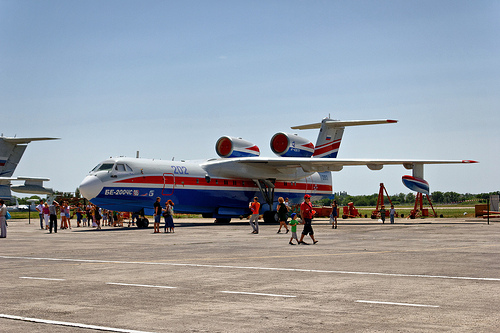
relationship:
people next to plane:
[29, 195, 84, 225] [67, 115, 396, 207]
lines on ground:
[166, 233, 406, 293] [5, 219, 497, 331]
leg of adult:
[310, 229, 317, 241] [297, 193, 319, 244]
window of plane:
[89, 146, 119, 190] [77, 111, 480, 226]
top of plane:
[287, 112, 399, 132] [58, 122, 425, 204]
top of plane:
[97, 120, 440, 170] [77, 111, 480, 226]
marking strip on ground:
[19, 276, 66, 281] [5, 219, 497, 331]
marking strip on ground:
[104, 280, 177, 290] [5, 219, 497, 331]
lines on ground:
[215, 291, 298, 300] [5, 219, 497, 331]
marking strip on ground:
[356, 294, 438, 308] [5, 219, 497, 331]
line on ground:
[0, 253, 500, 283] [5, 219, 497, 331]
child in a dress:
[288, 213, 302, 245] [276, 209, 307, 260]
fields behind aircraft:
[3, 204, 498, 224] [78, 117, 480, 226]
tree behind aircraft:
[73, 187, 81, 204] [78, 117, 480, 226]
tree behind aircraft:
[338, 191, 348, 208] [78, 117, 480, 226]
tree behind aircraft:
[397, 192, 405, 204] [78, 117, 480, 226]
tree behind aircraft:
[406, 193, 414, 203] [78, 117, 480, 226]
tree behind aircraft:
[442, 190, 452, 202] [78, 117, 480, 226]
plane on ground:
[56, 85, 499, 259] [107, 214, 414, 298]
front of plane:
[76, 154, 146, 213] [77, 111, 480, 226]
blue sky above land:
[2, 0, 498, 196] [0, 204, 499, 331]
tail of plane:
[287, 101, 397, 163] [77, 111, 480, 226]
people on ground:
[248, 192, 318, 245] [5, 219, 497, 331]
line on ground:
[4, 249, 497, 330] [5, 219, 497, 331]